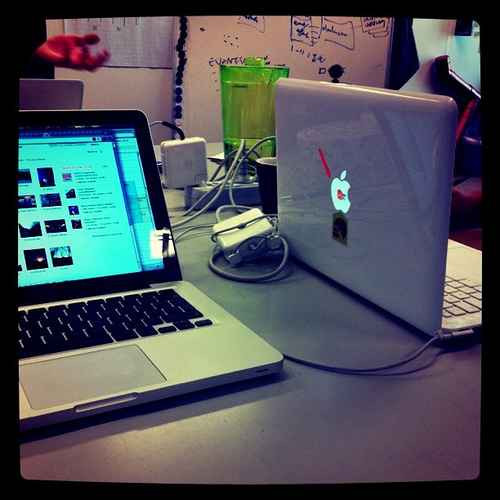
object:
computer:
[274, 76, 482, 343]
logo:
[331, 169, 353, 214]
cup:
[215, 63, 289, 177]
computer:
[16, 107, 284, 435]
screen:
[16, 129, 167, 290]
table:
[19, 142, 480, 486]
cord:
[208, 200, 291, 283]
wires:
[172, 130, 280, 244]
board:
[172, 16, 396, 144]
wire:
[285, 334, 442, 379]